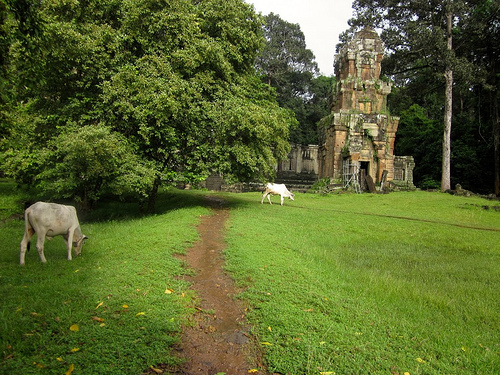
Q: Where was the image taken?
A: It was taken at the field.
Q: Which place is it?
A: It is a field.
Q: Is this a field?
A: Yes, it is a field.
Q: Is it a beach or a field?
A: It is a field.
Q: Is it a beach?
A: No, it is a field.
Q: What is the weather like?
A: It is cloudy.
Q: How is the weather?
A: It is cloudy.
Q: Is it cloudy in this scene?
A: Yes, it is cloudy.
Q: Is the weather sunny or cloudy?
A: It is cloudy.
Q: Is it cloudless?
A: No, it is cloudy.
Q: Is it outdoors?
A: Yes, it is outdoors.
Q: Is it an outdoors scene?
A: Yes, it is outdoors.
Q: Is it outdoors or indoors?
A: It is outdoors.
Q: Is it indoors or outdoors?
A: It is outdoors.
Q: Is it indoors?
A: No, it is outdoors.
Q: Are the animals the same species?
A: Yes, all the animals are cows.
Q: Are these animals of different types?
A: No, all the animals are cows.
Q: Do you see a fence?
A: No, there are no fences.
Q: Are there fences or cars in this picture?
A: No, there are no fences or cars.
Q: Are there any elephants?
A: No, there are no elephants.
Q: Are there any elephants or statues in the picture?
A: No, there are no elephants or statues.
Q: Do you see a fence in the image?
A: No, there are no fences.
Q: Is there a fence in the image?
A: No, there are no fences.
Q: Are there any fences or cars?
A: No, there are no fences or cars.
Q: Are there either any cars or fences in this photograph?
A: No, there are no fences or cars.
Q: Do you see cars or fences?
A: No, there are no fences or cars.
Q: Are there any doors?
A: Yes, there is a door.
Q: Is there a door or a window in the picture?
A: Yes, there is a door.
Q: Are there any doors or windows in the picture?
A: Yes, there is a door.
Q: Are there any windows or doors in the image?
A: Yes, there is a door.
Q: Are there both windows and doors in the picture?
A: No, there is a door but no windows.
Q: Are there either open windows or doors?
A: Yes, there is an open door.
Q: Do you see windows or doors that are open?
A: Yes, the door is open.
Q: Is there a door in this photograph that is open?
A: Yes, there is an open door.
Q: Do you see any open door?
A: Yes, there is an open door.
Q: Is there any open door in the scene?
A: Yes, there is an open door.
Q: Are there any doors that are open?
A: Yes, there is a door that is open.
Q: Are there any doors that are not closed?
A: Yes, there is a open door.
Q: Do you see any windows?
A: No, there are no windows.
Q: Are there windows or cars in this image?
A: No, there are no windows or cars.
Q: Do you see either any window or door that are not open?
A: No, there is a door but it is open.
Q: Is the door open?
A: Yes, the door is open.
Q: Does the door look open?
A: Yes, the door is open.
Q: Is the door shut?
A: No, the door is open.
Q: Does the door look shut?
A: No, the door is open.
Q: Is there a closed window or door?
A: No, there is a door but it is open.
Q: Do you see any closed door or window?
A: No, there is a door but it is open.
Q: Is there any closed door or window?
A: No, there is a door but it is open.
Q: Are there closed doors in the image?
A: No, there is a door but it is open.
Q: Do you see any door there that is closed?
A: No, there is a door but it is open.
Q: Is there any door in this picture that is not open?
A: No, there is a door but it is open.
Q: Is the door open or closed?
A: The door is open.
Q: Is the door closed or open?
A: The door is open.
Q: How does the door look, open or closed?
A: The door is open.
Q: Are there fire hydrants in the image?
A: No, there are no fire hydrants.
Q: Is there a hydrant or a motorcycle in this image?
A: No, there are no fire hydrants or motorcycles.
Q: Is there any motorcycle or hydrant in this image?
A: No, there are no fire hydrants or motorcycles.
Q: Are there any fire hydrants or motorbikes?
A: No, there are no fire hydrants or motorbikes.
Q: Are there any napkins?
A: No, there are no napkins.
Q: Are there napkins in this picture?
A: No, there are no napkins.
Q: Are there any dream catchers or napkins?
A: No, there are no napkins or dream catchers.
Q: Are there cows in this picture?
A: Yes, there is a cow.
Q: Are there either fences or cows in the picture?
A: Yes, there is a cow.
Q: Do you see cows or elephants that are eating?
A: Yes, the cow is eating.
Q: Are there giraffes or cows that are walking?
A: Yes, the cow is walking.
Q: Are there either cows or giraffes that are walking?
A: Yes, the cow is walking.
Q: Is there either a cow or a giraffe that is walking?
A: Yes, the cow is walking.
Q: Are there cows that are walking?
A: Yes, there is a cow that is walking.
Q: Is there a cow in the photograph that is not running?
A: Yes, there is a cow that is walking.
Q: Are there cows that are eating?
A: Yes, there is a cow that is eating.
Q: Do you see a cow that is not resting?
A: Yes, there is a cow that is eating .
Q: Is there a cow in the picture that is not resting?
A: Yes, there is a cow that is eating.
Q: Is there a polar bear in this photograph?
A: No, there are no polar bears.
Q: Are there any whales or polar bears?
A: No, there are no polar bears or whales.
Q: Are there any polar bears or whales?
A: No, there are no polar bears or whales.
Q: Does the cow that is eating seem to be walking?
A: Yes, the cow is walking.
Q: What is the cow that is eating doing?
A: The cow is walking.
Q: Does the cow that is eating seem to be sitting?
A: No, the cow is walking.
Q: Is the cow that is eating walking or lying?
A: The cow is walking.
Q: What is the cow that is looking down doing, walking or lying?
A: The cow is walking.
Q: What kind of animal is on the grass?
A: The animal is a cow.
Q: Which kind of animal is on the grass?
A: The animal is a cow.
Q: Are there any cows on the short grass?
A: Yes, there is a cow on the grass.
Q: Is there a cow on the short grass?
A: Yes, there is a cow on the grass.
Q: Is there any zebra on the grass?
A: No, there is a cow on the grass.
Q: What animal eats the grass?
A: The cow eats the grass.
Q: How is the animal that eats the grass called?
A: The animal is a cow.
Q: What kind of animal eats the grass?
A: The animal is a cow.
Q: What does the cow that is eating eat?
A: The cow eats grass.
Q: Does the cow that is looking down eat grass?
A: Yes, the cow eats grass.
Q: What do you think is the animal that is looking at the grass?
A: The animal is a cow.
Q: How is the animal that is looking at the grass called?
A: The animal is a cow.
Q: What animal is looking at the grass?
A: The animal is a cow.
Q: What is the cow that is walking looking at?
A: The cow is looking at the grass.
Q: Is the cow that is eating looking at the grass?
A: Yes, the cow is looking at the grass.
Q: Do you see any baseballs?
A: No, there are no baseballs.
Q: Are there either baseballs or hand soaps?
A: No, there are no baseballs or hand soaps.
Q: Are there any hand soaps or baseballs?
A: No, there are no baseballs or hand soaps.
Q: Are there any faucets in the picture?
A: No, there are no faucets.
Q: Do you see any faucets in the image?
A: No, there are no faucets.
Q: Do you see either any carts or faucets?
A: No, there are no faucets or carts.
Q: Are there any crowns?
A: No, there are no crowns.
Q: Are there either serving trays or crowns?
A: No, there are no crowns or serving trays.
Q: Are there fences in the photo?
A: No, there are no fences.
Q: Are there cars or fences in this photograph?
A: No, there are no fences or cars.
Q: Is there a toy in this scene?
A: No, there are no toys.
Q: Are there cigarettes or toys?
A: No, there are no toys or cigarettes.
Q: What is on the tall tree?
A: The leaves are on the tree.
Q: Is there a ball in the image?
A: No, there are no balls.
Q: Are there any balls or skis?
A: No, there are no balls or skis.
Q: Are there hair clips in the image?
A: No, there are no hair clips.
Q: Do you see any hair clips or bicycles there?
A: No, there are no hair clips or bicycles.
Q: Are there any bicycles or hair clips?
A: No, there are no hair clips or bicycles.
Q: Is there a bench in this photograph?
A: No, there are no benches.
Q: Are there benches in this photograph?
A: No, there are no benches.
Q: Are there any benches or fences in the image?
A: No, there are no benches or fences.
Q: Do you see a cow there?
A: Yes, there is a cow.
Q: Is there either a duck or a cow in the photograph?
A: Yes, there is a cow.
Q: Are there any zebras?
A: No, there are no zebras.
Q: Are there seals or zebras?
A: No, there are no zebras or seals.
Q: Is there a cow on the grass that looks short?
A: Yes, there is a cow on the grass.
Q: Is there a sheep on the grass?
A: No, there is a cow on the grass.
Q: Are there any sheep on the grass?
A: No, there is a cow on the grass.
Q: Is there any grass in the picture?
A: Yes, there is grass.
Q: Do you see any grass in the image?
A: Yes, there is grass.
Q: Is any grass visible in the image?
A: Yes, there is grass.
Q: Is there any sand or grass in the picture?
A: Yes, there is grass.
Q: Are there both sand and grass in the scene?
A: No, there is grass but no sand.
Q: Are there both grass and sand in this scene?
A: No, there is grass but no sand.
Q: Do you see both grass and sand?
A: No, there is grass but no sand.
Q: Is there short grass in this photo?
A: Yes, there is short grass.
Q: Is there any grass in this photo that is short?
A: Yes, there is grass that is short.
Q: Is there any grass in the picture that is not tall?
A: Yes, there is short grass.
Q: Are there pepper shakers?
A: No, there are no pepper shakers.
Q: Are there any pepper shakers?
A: No, there are no pepper shakers.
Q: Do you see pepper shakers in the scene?
A: No, there are no pepper shakers.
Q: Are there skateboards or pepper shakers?
A: No, there are no pepper shakers or skateboards.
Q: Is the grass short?
A: Yes, the grass is short.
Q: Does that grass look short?
A: Yes, the grass is short.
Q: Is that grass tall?
A: No, the grass is short.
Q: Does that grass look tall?
A: No, the grass is short.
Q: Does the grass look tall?
A: No, the grass is short.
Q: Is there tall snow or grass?
A: No, there is grass but it is short.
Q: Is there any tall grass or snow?
A: No, there is grass but it is short.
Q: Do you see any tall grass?
A: No, there is grass but it is short.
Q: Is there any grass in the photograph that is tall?
A: No, there is grass but it is short.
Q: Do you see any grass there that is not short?
A: No, there is grass but it is short.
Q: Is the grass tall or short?
A: The grass is short.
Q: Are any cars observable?
A: No, there are no cars.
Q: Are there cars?
A: No, there are no cars.